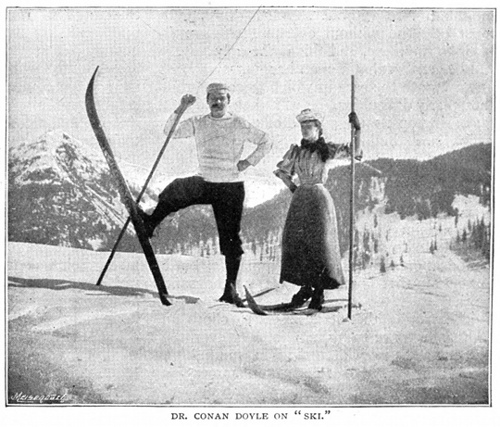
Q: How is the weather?
A: It is sunny.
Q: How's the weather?
A: It is sunny.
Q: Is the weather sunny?
A: Yes, it is sunny.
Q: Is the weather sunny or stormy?
A: It is sunny.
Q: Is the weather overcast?
A: No, it is sunny.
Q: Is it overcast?
A: No, it is sunny.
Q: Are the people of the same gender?
A: No, they are both male and female.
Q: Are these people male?
A: No, they are both male and female.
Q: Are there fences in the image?
A: No, there are no fences.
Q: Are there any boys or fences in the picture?
A: No, there are no fences or boys.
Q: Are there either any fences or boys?
A: No, there are no fences or boys.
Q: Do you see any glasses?
A: No, there are no glasses.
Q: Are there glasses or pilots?
A: No, there are no glasses or pilots.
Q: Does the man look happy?
A: Yes, the man is happy.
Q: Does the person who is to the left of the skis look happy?
A: Yes, the man is happy.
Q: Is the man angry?
A: No, the man is happy.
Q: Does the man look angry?
A: No, the man is happy.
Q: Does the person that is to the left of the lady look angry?
A: No, the man is happy.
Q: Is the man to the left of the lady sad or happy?
A: The man is happy.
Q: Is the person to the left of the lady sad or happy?
A: The man is happy.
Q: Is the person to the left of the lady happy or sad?
A: The man is happy.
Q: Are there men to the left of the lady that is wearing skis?
A: Yes, there is a man to the left of the lady.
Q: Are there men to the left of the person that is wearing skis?
A: Yes, there is a man to the left of the lady.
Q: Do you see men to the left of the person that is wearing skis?
A: Yes, there is a man to the left of the lady.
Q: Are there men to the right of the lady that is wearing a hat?
A: No, the man is to the left of the lady.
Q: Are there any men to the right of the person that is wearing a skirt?
A: No, the man is to the left of the lady.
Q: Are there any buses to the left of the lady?
A: No, there is a man to the left of the lady.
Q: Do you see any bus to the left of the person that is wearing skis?
A: No, there is a man to the left of the lady.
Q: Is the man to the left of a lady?
A: Yes, the man is to the left of a lady.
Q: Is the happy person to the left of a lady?
A: Yes, the man is to the left of a lady.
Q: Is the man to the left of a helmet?
A: No, the man is to the left of a lady.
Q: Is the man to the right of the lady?
A: No, the man is to the left of the lady.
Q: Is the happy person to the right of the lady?
A: No, the man is to the left of the lady.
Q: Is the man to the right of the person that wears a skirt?
A: No, the man is to the left of the lady.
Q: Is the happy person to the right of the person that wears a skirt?
A: No, the man is to the left of the lady.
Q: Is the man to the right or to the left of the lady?
A: The man is to the left of the lady.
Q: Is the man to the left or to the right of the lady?
A: The man is to the left of the lady.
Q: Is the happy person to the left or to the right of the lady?
A: The man is to the left of the lady.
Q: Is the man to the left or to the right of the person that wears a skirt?
A: The man is to the left of the lady.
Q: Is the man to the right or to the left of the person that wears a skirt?
A: The man is to the left of the lady.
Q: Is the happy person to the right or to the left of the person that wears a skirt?
A: The man is to the left of the lady.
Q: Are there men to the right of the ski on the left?
A: Yes, there is a man to the right of the ski.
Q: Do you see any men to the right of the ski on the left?
A: Yes, there is a man to the right of the ski.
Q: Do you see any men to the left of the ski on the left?
A: No, the man is to the right of the ski.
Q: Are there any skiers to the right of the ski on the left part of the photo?
A: No, there is a man to the right of the ski.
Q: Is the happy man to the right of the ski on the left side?
A: Yes, the man is to the right of the ski.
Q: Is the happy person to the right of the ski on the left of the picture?
A: Yes, the man is to the right of the ski.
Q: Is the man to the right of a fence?
A: No, the man is to the right of the ski.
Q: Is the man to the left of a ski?
A: No, the man is to the right of a ski.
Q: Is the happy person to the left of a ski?
A: No, the man is to the right of a ski.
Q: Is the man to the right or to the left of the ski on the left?
A: The man is to the right of the ski.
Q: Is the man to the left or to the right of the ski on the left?
A: The man is to the right of the ski.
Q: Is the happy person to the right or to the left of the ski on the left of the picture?
A: The man is to the right of the ski.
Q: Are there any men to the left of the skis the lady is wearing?
A: Yes, there is a man to the left of the skis.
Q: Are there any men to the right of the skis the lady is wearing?
A: No, the man is to the left of the skis.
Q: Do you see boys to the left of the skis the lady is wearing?
A: No, there is a man to the left of the skis.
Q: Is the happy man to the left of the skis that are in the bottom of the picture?
A: Yes, the man is to the left of the skis.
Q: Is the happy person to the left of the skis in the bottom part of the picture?
A: Yes, the man is to the left of the skis.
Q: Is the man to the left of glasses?
A: No, the man is to the left of the skis.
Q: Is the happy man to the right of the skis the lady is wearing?
A: No, the man is to the left of the skis.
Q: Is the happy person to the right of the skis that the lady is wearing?
A: No, the man is to the left of the skis.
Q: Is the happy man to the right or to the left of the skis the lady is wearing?
A: The man is to the left of the skis.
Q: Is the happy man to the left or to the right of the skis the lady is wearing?
A: The man is to the left of the skis.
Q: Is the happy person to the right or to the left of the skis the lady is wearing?
A: The man is to the left of the skis.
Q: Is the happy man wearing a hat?
A: Yes, the man is wearing a hat.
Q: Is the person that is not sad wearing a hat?
A: Yes, the man is wearing a hat.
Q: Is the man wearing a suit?
A: No, the man is wearing a hat.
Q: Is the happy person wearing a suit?
A: No, the man is wearing a hat.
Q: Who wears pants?
A: The man wears pants.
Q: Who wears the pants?
A: The man wears pants.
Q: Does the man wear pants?
A: Yes, the man wears pants.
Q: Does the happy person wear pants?
A: Yes, the man wears pants.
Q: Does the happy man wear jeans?
A: No, the man wears pants.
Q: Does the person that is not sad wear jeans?
A: No, the man wears pants.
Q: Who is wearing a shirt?
A: The man is wearing a shirt.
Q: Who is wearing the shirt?
A: The man is wearing a shirt.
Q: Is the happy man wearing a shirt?
A: Yes, the man is wearing a shirt.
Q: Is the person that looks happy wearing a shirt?
A: Yes, the man is wearing a shirt.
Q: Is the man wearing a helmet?
A: No, the man is wearing a shirt.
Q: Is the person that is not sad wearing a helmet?
A: No, the man is wearing a shirt.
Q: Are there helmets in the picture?
A: No, there are no helmets.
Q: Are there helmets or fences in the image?
A: No, there are no helmets or fences.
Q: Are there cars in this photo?
A: No, there are no cars.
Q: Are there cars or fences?
A: No, there are no cars or fences.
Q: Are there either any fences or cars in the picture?
A: No, there are no cars or fences.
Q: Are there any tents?
A: No, there are no tents.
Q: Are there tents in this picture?
A: No, there are no tents.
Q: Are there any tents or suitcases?
A: No, there are no tents or suitcases.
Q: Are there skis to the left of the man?
A: Yes, there is a ski to the left of the man.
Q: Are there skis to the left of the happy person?
A: Yes, there is a ski to the left of the man.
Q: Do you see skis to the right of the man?
A: No, the ski is to the left of the man.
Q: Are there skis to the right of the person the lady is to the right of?
A: No, the ski is to the left of the man.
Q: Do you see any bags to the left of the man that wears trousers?
A: No, there is a ski to the left of the man.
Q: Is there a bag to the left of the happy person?
A: No, there is a ski to the left of the man.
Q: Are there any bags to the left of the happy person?
A: No, there is a ski to the left of the man.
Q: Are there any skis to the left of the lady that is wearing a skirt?
A: Yes, there is a ski to the left of the lady.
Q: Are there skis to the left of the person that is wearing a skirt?
A: Yes, there is a ski to the left of the lady.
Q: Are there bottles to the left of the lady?
A: No, there is a ski to the left of the lady.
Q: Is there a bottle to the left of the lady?
A: No, there is a ski to the left of the lady.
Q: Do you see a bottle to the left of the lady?
A: No, there is a ski to the left of the lady.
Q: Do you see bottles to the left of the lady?
A: No, there is a ski to the left of the lady.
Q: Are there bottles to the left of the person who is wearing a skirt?
A: No, there is a ski to the left of the lady.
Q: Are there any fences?
A: No, there are no fences.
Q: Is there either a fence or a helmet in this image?
A: No, there are no fences or helmets.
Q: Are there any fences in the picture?
A: No, there are no fences.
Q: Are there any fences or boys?
A: No, there are no fences or boys.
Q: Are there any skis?
A: Yes, there are skis.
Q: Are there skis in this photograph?
A: Yes, there are skis.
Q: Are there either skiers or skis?
A: Yes, there are skis.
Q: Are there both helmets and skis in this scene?
A: No, there are skis but no helmets.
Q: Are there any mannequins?
A: No, there are no mannequins.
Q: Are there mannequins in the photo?
A: No, there are no mannequins.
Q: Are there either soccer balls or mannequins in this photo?
A: No, there are no mannequins or soccer balls.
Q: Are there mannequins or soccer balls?
A: No, there are no mannequins or soccer balls.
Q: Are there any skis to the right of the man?
A: Yes, there are skis to the right of the man.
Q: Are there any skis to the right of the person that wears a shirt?
A: Yes, there are skis to the right of the man.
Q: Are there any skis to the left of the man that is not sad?
A: No, the skis are to the right of the man.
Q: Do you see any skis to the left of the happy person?
A: No, the skis are to the right of the man.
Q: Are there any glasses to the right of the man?
A: No, there are skis to the right of the man.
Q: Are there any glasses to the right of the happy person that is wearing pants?
A: No, there are skis to the right of the man.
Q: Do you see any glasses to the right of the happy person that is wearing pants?
A: No, there are skis to the right of the man.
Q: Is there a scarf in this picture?
A: Yes, there is a scarf.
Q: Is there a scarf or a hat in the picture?
A: Yes, there is a scarf.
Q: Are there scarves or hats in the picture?
A: Yes, there is a scarf.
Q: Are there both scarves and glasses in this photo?
A: No, there is a scarf but no glasses.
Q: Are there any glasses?
A: No, there are no glasses.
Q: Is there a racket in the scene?
A: No, there are no rackets.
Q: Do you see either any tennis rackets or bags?
A: No, there are no tennis rackets or bags.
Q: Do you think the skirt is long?
A: Yes, the skirt is long.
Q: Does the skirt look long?
A: Yes, the skirt is long.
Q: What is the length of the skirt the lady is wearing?
A: The skirt is long.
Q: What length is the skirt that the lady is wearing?
A: The skirt is long.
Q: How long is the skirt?
A: The skirt is long.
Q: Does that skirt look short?
A: No, the skirt is long.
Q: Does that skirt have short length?
A: No, the skirt is long.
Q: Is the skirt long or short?
A: The skirt is long.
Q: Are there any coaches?
A: No, there are no coaches.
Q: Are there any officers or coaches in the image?
A: No, there are no coaches or officers.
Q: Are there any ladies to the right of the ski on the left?
A: Yes, there is a lady to the right of the ski.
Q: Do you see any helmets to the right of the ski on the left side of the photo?
A: No, there is a lady to the right of the ski.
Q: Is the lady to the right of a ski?
A: Yes, the lady is to the right of a ski.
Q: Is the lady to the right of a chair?
A: No, the lady is to the right of a ski.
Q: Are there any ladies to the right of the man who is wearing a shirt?
A: Yes, there is a lady to the right of the man.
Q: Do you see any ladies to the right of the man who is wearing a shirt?
A: Yes, there is a lady to the right of the man.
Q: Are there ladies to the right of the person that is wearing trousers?
A: Yes, there is a lady to the right of the man.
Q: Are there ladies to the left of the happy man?
A: No, the lady is to the right of the man.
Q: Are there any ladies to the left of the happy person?
A: No, the lady is to the right of the man.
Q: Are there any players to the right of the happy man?
A: No, there is a lady to the right of the man.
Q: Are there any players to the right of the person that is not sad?
A: No, there is a lady to the right of the man.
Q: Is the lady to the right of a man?
A: Yes, the lady is to the right of a man.